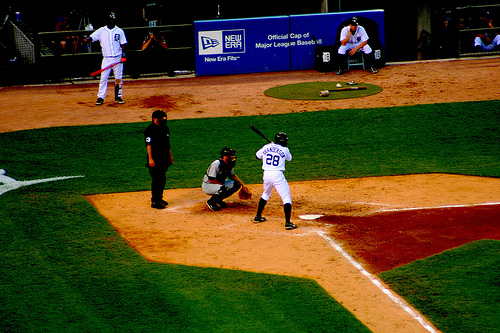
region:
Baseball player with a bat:
[247, 119, 296, 230]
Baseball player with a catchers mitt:
[199, 144, 253, 211]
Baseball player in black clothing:
[144, 106, 177, 211]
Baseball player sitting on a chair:
[335, 14, 377, 76]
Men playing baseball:
[137, 102, 299, 232]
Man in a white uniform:
[81, 9, 129, 105]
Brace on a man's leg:
[112, 80, 125, 105]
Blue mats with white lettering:
[192, 8, 385, 78]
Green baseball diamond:
[1, 100, 497, 331]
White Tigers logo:
[320, 49, 330, 64]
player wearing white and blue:
[92, 13, 129, 105]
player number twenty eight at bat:
[253, 124, 297, 229]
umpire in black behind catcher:
[144, 109, 175, 209]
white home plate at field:
[296, 211, 326, 223]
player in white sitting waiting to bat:
[335, 17, 377, 78]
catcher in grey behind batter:
[196, 145, 251, 210]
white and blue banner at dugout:
[194, 18, 290, 75]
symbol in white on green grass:
[0, 167, 83, 204]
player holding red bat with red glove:
[86, 12, 129, 105]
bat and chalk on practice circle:
[264, 80, 384, 100]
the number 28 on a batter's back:
[262, 154, 283, 168]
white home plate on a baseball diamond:
[294, 205, 330, 231]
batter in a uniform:
[239, 105, 304, 235]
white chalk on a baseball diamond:
[353, 258, 417, 325]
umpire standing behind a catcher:
[138, 96, 172, 211]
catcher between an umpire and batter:
[198, 137, 256, 219]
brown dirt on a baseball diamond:
[357, 175, 417, 245]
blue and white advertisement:
[185, 13, 297, 98]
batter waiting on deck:
[82, 11, 137, 117]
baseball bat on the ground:
[318, 79, 374, 106]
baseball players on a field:
[1, 9, 498, 331]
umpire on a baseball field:
[142, 106, 178, 212]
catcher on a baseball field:
[195, 143, 255, 210]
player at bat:
[240, 121, 297, 230]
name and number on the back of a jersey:
[259, 144, 286, 169]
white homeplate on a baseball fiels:
[298, 211, 323, 223]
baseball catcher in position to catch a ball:
[200, 146, 255, 214]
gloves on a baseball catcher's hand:
[238, 182, 253, 205]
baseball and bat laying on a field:
[322, 81, 371, 93]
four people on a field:
[77, 9, 306, 231]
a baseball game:
[5, 3, 499, 240]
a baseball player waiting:
[308, 17, 386, 76]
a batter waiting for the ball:
[242, 119, 299, 231]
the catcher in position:
[195, 146, 253, 215]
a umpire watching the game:
[140, 110, 178, 207]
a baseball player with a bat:
[242, 118, 302, 230]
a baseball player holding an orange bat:
[74, 10, 135, 106]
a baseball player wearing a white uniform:
[244, 121, 301, 234]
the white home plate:
[297, 207, 325, 224]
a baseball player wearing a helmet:
[242, 115, 309, 231]